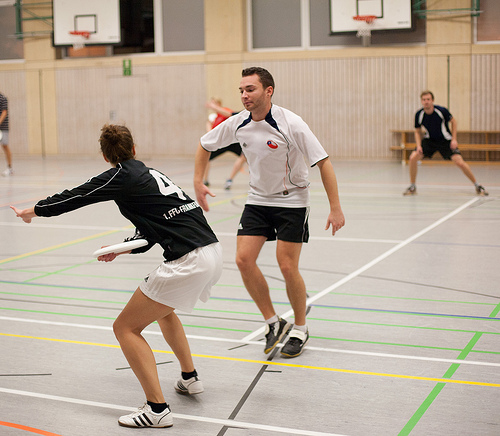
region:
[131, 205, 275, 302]
A pair of white shorts.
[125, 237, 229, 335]
A pair of white shorts.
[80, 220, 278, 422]
A pair of white shorts.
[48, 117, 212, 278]
A pair of white shorts.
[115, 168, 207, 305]
A pair of white shorts.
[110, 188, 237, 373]
A pair of white shorts.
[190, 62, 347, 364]
man is in motion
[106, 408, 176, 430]
shoes has three stripes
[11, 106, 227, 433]
woman has on black socks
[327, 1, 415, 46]
basketball hoop is on wall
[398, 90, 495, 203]
man is slightly lunging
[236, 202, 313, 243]
shorts are black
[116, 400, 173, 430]
stripes on shoes are black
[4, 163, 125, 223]
arm is stretched out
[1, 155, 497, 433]
court has lines painted on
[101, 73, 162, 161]
door is on wall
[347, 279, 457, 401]
colored criss crossing lines on the floor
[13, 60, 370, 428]
people playing a game of frisbee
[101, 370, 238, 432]
white and black sneakers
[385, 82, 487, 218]
man at the gym in a ready stance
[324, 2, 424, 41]
basketball hoop and back board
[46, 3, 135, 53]
basketball hoop in the gym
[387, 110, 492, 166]
wooden benches in the gym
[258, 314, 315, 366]
black gym shoes and white socks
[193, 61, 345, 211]
man in a white exercise shirt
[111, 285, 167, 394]
woman's shaved leg in shorts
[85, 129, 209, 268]
woman preparing to throw a frisbee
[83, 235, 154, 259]
white frisbee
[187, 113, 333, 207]
black and white shirt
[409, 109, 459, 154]
black shirt with white stripe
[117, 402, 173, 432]
white shoes with black stripes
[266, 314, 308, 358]
black shoes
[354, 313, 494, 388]
green lines on the ground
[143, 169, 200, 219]
white number four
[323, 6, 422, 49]
black and white basketball net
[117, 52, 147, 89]
green sign on wall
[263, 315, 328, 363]
the man is wearing black sneakers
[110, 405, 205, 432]
the man is wearing white shoes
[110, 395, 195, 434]
his shoes have white stripes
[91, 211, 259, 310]
the man is wearing white shorts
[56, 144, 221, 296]
the man is wearing a black jacket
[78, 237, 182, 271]
the man is about to fling a frisbee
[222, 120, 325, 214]
the man is wearing a white shirt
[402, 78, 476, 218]
this man is wearing all black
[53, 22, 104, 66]
a basketball hoop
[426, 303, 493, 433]
a green stripe is on the floor